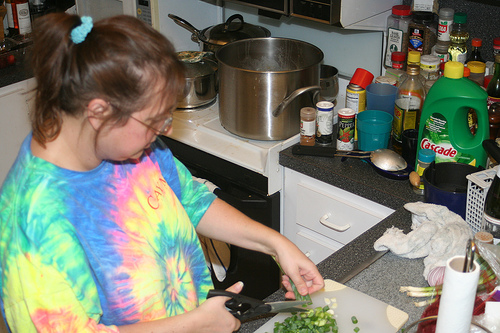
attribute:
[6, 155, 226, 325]
shirt — tie dye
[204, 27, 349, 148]
pot — large, gray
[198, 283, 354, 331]
scissors — black and silver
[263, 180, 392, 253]
drawer — white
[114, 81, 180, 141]
eyeglasses — woman's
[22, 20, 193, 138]
hair — brown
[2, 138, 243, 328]
shirt — woman's, colorful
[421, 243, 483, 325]
paper towels — roll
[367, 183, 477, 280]
rag — white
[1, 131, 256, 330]
top — tie dyed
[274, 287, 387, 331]
onions — green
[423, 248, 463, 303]
paper towels — roll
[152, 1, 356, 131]
pots — various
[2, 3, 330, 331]
lady — wears glasses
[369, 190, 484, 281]
dish rag — lays messily, on the counter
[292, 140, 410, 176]
metal spoon — large, for stirring the pot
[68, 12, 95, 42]
scrunchy — makes lady's pony tail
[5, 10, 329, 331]
girl — cutting vegetables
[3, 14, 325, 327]
woman — using scissors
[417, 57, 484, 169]
large container — of dishwasher detergent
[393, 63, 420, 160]
bottle/olive oil — on the counter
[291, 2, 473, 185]
spices/condiments — a variety, on the right